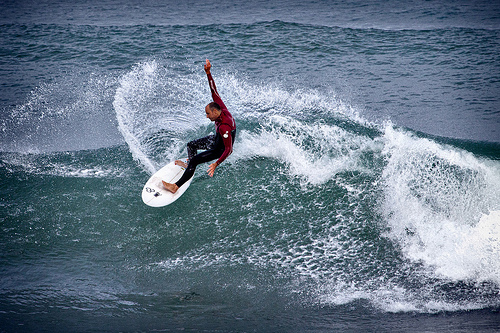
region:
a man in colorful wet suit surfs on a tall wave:
[158, 61, 248, 211]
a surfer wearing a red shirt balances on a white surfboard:
[166, 60, 237, 200]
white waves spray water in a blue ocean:
[376, 114, 488, 300]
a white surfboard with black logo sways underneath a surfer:
[141, 155, 188, 216]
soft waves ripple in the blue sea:
[31, 9, 493, 63]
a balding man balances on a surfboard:
[137, 69, 228, 214]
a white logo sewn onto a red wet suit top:
[223, 127, 229, 141]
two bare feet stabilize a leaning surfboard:
[160, 156, 181, 197]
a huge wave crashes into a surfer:
[95, 95, 482, 236]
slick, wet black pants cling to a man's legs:
[161, 126, 216, 202]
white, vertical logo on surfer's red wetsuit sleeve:
[205, 75, 222, 98]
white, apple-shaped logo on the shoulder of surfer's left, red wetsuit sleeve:
[218, 129, 231, 139]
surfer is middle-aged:
[202, 100, 224, 122]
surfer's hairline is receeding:
[199, 102, 212, 111]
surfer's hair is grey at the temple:
[207, 105, 217, 110]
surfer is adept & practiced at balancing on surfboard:
[156, 139, 213, 199]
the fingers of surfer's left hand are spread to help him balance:
[201, 161, 218, 180]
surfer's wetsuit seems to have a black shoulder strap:
[212, 121, 232, 135]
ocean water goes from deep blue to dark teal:
[0, 212, 356, 332]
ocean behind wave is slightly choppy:
[247, 0, 499, 132]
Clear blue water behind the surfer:
[61, 16, 425, 51]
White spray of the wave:
[382, 127, 475, 254]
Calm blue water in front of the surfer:
[18, 256, 210, 323]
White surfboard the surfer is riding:
[140, 166, 167, 208]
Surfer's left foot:
[158, 176, 180, 195]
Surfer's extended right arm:
[200, 57, 222, 97]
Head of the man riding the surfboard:
[203, 103, 223, 123]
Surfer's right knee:
[179, 134, 204, 154]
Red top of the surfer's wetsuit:
[213, 121, 238, 135]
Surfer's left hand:
[203, 161, 225, 180]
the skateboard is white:
[141, 155, 197, 201]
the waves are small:
[246, 90, 443, 236]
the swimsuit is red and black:
[196, 120, 240, 160]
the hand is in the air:
[195, 60, 227, 97]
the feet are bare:
[161, 158, 196, 195]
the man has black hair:
[200, 101, 229, 114]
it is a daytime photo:
[4, 2, 499, 331]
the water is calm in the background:
[241, 22, 448, 67]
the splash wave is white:
[403, 202, 496, 252]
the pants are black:
[176, 145, 226, 177]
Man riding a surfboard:
[123, 41, 250, 238]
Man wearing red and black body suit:
[117, 31, 269, 256]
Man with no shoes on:
[130, 53, 257, 223]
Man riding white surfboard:
[130, 28, 270, 231]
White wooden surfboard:
[130, 148, 205, 215]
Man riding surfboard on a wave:
[117, 46, 267, 244]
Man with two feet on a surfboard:
[122, 38, 259, 243]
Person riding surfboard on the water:
[93, 22, 278, 258]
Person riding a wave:
[118, 43, 263, 232]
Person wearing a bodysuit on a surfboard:
[109, 34, 270, 248]